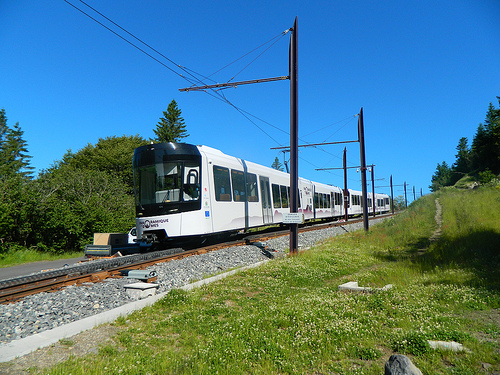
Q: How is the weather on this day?
A: It is clear.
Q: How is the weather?
A: It is clear.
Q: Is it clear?
A: Yes, it is clear.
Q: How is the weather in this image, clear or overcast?
A: It is clear.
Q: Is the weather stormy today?
A: No, it is clear.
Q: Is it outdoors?
A: Yes, it is outdoors.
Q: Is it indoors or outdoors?
A: It is outdoors.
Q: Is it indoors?
A: No, it is outdoors.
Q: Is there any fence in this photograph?
A: No, there are no fences.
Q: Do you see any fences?
A: No, there are no fences.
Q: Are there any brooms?
A: No, there are no brooms.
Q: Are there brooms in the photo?
A: No, there are no brooms.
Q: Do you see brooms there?
A: No, there are no brooms.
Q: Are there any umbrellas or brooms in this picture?
A: No, there are no brooms or umbrellas.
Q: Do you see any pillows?
A: No, there are no pillows.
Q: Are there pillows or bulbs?
A: No, there are no pillows or bulbs.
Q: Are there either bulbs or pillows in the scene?
A: No, there are no pillows or bulbs.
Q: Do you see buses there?
A: Yes, there is a bus.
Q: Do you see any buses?
A: Yes, there is a bus.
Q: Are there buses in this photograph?
A: Yes, there is a bus.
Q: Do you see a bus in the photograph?
A: Yes, there is a bus.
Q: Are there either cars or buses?
A: Yes, there is a bus.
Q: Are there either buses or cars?
A: Yes, there is a bus.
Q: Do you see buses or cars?
A: Yes, there is a bus.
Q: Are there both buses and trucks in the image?
A: No, there is a bus but no trucks.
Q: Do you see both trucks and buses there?
A: No, there is a bus but no trucks.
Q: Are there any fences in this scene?
A: No, there are no fences.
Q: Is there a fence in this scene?
A: No, there are no fences.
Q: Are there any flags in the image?
A: No, there are no flags.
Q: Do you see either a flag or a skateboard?
A: No, there are no flags or skateboards.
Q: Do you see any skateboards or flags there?
A: No, there are no flags or skateboards.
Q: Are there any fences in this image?
A: No, there are no fences.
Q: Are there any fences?
A: No, there are no fences.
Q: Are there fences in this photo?
A: No, there are no fences.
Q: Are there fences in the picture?
A: No, there are no fences.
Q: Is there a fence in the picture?
A: No, there are no fences.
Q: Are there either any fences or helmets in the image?
A: No, there are no fences or helmets.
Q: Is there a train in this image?
A: Yes, there is a train.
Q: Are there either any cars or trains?
A: Yes, there is a train.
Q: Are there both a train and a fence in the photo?
A: No, there is a train but no fences.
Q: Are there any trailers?
A: No, there are no trailers.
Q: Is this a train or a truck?
A: This is a train.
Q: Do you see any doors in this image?
A: Yes, there is a door.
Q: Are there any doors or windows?
A: Yes, there is a door.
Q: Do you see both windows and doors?
A: Yes, there are both a door and windows.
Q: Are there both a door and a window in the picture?
A: Yes, there are both a door and a window.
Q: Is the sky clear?
A: Yes, the sky is clear.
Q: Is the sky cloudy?
A: No, the sky is clear.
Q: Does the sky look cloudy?
A: No, the sky is clear.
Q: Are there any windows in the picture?
A: Yes, there is a window.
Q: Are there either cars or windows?
A: Yes, there is a window.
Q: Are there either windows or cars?
A: Yes, there is a window.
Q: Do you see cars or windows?
A: Yes, there is a window.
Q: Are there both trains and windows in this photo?
A: Yes, there are both a window and a train.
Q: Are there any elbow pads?
A: No, there are no elbow pads.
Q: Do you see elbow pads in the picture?
A: No, there are no elbow pads.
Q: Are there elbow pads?
A: No, there are no elbow pads.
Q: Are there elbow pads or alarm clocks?
A: No, there are no elbow pads or alarm clocks.